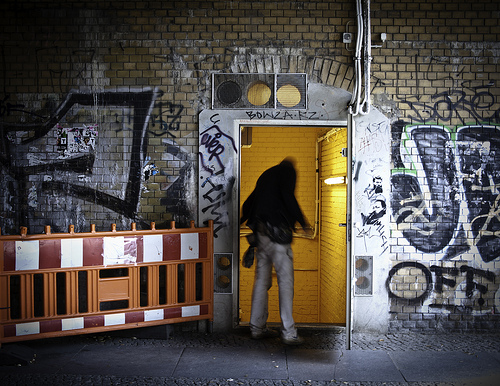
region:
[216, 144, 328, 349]
a person walking into a building.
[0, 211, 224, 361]
a plastic gate on a building.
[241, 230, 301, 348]
a person wearing pants.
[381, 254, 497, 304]
the word off in spray paint.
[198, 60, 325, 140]
windows above a door.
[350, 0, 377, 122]
pipes on the side of a building.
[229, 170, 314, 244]
a black jacket.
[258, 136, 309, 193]
the head of a monster.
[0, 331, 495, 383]
a sidewalk outside of a building.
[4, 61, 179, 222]
spray paint on a building.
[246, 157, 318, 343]
this is a person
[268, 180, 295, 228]
the top is black in color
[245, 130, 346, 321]
this is a door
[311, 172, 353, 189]
this is a bulb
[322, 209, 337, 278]
the wall is bright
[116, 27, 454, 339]
this is a building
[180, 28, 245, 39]
the wall is made of bricks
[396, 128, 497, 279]
the wall is full of writings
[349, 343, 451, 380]
this is a pavement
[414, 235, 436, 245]
the writings are black in color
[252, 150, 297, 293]
A person heading downstairs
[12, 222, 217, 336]
A construction/safety gate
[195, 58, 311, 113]
Vents for the building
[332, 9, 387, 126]
Electrical wires for the building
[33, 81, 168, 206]
Grafetee on the walls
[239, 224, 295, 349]
A pair of white colored pants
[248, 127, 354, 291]
A well lit stairwell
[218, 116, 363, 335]
Entrance to the building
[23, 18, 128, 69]
A brick wall of the building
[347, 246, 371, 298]
More vetns for the building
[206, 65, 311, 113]
a vent with three holes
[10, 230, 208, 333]
an orange caution gate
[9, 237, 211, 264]
a red and white checkered strip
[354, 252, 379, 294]
a vent on the side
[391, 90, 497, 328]
graffitti on the wall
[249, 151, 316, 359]
a man walking into a building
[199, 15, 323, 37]
beige bricks in the wall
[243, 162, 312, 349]
a man wearing white pants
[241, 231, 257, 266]
a black plastic bag dangling down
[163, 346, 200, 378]
a line in the sidewalk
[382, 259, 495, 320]
the word OFF spray painted on the wall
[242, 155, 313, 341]
a person standing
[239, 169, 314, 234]
the black jacket of a person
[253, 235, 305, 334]
the white pants of a person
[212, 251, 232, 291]
a wire grate covering a hole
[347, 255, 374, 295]
a wire grate covering a hole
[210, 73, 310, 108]
a wire grate covering a hole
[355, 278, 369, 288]
a hole in the wall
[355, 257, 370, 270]
a hole in the wall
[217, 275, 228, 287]
a hole in the wall